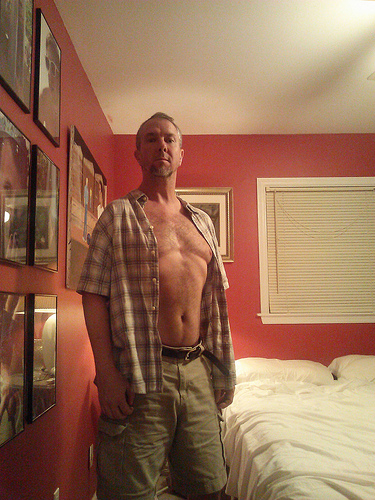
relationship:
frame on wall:
[179, 185, 237, 266] [185, 133, 250, 225]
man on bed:
[72, 108, 243, 493] [221, 348, 371, 498]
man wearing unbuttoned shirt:
[76, 111, 238, 499] [78, 190, 236, 391]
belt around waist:
[165, 347, 204, 361] [114, 347, 222, 360]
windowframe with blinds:
[260, 153, 373, 331] [274, 235, 372, 311]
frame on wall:
[68, 131, 104, 282] [59, 302, 91, 496]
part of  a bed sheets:
[247, 358, 343, 454] [221, 380, 374, 500]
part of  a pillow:
[244, 340, 303, 419] [222, 333, 349, 414]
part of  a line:
[204, 415, 224, 500] [190, 436, 217, 451]